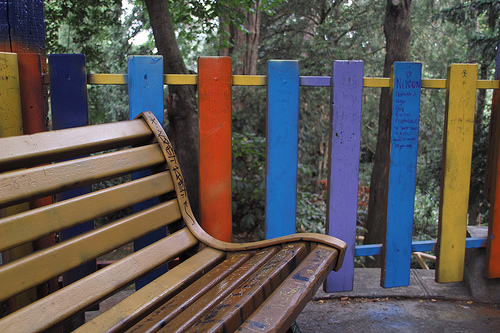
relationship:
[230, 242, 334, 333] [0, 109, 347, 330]
graffiti all over bench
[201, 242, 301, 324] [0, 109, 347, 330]
graffiti all over bench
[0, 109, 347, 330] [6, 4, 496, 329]
bench on patio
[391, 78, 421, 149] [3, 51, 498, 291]
graffiti on fence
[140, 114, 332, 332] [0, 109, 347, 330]
writing on bench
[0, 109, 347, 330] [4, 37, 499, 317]
bench next to fence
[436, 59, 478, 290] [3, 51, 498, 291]
post of fence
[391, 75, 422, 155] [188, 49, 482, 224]
writing on fence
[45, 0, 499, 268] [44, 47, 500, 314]
tree behind picket fence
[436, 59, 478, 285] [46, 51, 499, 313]
post of fence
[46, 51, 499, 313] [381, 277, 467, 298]
fence around patio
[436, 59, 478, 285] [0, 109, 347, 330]
post behind bench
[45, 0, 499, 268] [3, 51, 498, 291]
tree behind fence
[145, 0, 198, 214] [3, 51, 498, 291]
tree behind fence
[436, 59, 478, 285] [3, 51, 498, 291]
post on fence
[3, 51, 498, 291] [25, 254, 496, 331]
fence around patio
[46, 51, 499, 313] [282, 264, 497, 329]
fence above ground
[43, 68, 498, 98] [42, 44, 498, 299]
beam holds posts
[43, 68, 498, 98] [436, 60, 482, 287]
beam holds post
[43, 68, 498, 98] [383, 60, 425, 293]
beam holds post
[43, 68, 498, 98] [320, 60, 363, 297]
beam holds post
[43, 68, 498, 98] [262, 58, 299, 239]
beam holds post